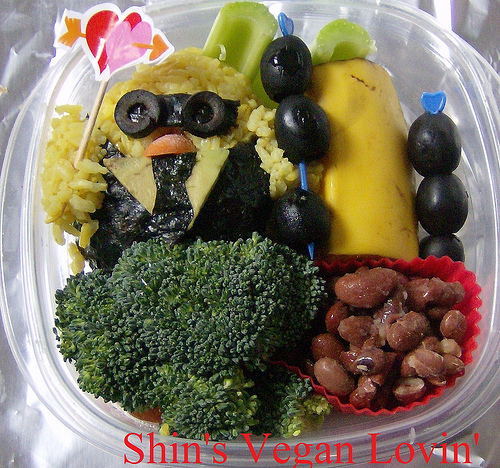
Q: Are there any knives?
A: No, there are no knives.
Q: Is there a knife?
A: No, there are no knives.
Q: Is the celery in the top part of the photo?
A: Yes, the celery is in the top of the image.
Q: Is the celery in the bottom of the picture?
A: No, the celery is in the top of the image.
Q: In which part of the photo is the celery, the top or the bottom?
A: The celery is in the top of the image.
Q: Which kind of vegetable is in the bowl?
A: The vegetable is a celery.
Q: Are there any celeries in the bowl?
A: Yes, there is a celery in the bowl.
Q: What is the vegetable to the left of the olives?
A: The vegetable is a celery.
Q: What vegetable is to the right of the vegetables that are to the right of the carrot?
A: The vegetable is an olive.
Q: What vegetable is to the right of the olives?
A: The vegetable is an olive.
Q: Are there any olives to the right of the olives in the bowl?
A: Yes, there is an olive to the right of the olives.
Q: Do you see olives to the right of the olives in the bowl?
A: Yes, there is an olive to the right of the olives.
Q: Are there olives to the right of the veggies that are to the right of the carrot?
A: Yes, there is an olive to the right of the olives.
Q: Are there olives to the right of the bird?
A: Yes, there is an olive to the right of the bird.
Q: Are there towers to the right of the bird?
A: No, there is an olive to the right of the bird.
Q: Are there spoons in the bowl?
A: No, there is an olive in the bowl.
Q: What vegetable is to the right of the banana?
A: The vegetable is an olive.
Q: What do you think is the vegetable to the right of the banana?
A: The vegetable is an olive.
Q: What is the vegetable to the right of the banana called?
A: The vegetable is an olive.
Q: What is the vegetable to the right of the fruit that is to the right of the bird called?
A: The vegetable is an olive.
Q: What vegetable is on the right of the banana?
A: The vegetable is an olive.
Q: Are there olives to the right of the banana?
A: Yes, there is an olive to the right of the banana.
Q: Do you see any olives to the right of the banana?
A: Yes, there is an olive to the right of the banana.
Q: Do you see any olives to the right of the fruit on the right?
A: Yes, there is an olive to the right of the banana.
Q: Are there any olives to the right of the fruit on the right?
A: Yes, there is an olive to the right of the banana.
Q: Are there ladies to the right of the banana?
A: No, there is an olive to the right of the banana.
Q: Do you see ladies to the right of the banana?
A: No, there is an olive to the right of the banana.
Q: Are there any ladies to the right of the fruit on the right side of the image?
A: No, there is an olive to the right of the banana.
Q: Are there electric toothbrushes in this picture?
A: No, there are no electric toothbrushes.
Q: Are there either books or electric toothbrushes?
A: No, there are no electric toothbrushes or books.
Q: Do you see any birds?
A: Yes, there is a bird.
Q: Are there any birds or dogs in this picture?
A: Yes, there is a bird.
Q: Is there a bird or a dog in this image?
A: Yes, there is a bird.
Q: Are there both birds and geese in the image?
A: No, there is a bird but no geese.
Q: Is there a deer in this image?
A: No, there is no deer.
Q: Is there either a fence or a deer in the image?
A: No, there are no deer or fences.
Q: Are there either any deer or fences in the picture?
A: No, there are no deer or fences.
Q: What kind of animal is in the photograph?
A: The animal is a bird.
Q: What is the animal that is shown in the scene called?
A: The animal is a bird.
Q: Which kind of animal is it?
A: The animal is a bird.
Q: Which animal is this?
A: This is a bird.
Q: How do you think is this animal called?
A: This is a bird.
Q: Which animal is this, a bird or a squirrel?
A: This is a bird.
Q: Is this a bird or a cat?
A: This is a bird.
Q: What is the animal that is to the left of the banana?
A: The animal is a bird.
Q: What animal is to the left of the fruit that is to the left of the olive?
A: The animal is a bird.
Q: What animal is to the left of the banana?
A: The animal is a bird.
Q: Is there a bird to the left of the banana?
A: Yes, there is a bird to the left of the banana.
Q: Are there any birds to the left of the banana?
A: Yes, there is a bird to the left of the banana.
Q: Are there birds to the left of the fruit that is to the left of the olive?
A: Yes, there is a bird to the left of the banana.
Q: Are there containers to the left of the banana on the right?
A: No, there is a bird to the left of the banana.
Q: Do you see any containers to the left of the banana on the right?
A: No, there is a bird to the left of the banana.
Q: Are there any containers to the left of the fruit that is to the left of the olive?
A: No, there is a bird to the left of the banana.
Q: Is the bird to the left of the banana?
A: Yes, the bird is to the left of the banana.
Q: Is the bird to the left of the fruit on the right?
A: Yes, the bird is to the left of the banana.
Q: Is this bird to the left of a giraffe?
A: No, the bird is to the left of the banana.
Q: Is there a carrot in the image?
A: Yes, there is a carrot.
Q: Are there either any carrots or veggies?
A: Yes, there is a carrot.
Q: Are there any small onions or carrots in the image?
A: Yes, there is a small carrot.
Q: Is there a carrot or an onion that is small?
A: Yes, the carrot is small.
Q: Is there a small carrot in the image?
A: Yes, there is a small carrot.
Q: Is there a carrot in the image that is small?
A: Yes, there is a carrot that is small.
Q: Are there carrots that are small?
A: Yes, there is a carrot that is small.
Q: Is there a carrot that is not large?
A: Yes, there is a small carrot.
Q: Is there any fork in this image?
A: No, there are no forks.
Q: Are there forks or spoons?
A: No, there are no forks or spoons.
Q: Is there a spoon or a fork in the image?
A: No, there are no forks or spoons.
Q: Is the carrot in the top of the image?
A: Yes, the carrot is in the top of the image.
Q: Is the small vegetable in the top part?
A: Yes, the carrot is in the top of the image.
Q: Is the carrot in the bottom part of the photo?
A: No, the carrot is in the top of the image.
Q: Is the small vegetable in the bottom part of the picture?
A: No, the carrot is in the top of the image.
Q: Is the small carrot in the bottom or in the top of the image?
A: The carrot is in the top of the image.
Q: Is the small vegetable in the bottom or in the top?
A: The carrot is in the top of the image.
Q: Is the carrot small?
A: Yes, the carrot is small.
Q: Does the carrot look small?
A: Yes, the carrot is small.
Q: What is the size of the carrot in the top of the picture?
A: The carrot is small.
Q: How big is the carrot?
A: The carrot is small.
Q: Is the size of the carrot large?
A: No, the carrot is small.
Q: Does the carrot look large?
A: No, the carrot is small.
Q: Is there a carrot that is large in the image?
A: No, there is a carrot but it is small.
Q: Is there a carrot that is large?
A: No, there is a carrot but it is small.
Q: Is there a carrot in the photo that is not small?
A: No, there is a carrot but it is small.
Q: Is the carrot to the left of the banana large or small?
A: The carrot is small.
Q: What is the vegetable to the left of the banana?
A: The vegetable is a carrot.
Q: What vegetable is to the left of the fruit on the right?
A: The vegetable is a carrot.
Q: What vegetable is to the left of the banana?
A: The vegetable is a carrot.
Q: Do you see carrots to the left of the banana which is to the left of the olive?
A: Yes, there is a carrot to the left of the banana.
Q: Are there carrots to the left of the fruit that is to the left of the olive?
A: Yes, there is a carrot to the left of the banana.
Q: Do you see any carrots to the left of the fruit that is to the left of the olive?
A: Yes, there is a carrot to the left of the banana.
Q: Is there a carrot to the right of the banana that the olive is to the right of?
A: No, the carrot is to the left of the banana.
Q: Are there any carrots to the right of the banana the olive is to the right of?
A: No, the carrot is to the left of the banana.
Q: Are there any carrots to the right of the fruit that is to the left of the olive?
A: No, the carrot is to the left of the banana.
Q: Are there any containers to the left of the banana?
A: No, there is a carrot to the left of the banana.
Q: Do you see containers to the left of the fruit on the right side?
A: No, there is a carrot to the left of the banana.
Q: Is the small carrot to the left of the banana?
A: Yes, the carrot is to the left of the banana.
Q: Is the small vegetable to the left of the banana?
A: Yes, the carrot is to the left of the banana.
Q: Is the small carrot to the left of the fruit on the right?
A: Yes, the carrot is to the left of the banana.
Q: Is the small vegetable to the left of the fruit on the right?
A: Yes, the carrot is to the left of the banana.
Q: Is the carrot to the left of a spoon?
A: No, the carrot is to the left of the banana.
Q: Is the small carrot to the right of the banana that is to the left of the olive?
A: No, the carrot is to the left of the banana.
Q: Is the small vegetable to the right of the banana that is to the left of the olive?
A: No, the carrot is to the left of the banana.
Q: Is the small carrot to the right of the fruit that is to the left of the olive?
A: No, the carrot is to the left of the banana.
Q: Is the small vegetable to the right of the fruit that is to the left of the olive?
A: No, the carrot is to the left of the banana.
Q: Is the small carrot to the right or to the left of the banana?
A: The carrot is to the left of the banana.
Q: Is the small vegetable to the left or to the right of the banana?
A: The carrot is to the left of the banana.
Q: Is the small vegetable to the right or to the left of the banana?
A: The carrot is to the left of the banana.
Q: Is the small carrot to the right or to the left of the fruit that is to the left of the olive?
A: The carrot is to the left of the banana.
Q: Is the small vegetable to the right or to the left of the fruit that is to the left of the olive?
A: The carrot is to the left of the banana.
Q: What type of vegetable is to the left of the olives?
A: The vegetable is a carrot.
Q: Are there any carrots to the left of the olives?
A: Yes, there is a carrot to the left of the olives.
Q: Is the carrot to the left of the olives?
A: Yes, the carrot is to the left of the olives.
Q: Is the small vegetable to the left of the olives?
A: Yes, the carrot is to the left of the olives.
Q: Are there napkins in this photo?
A: No, there are no napkins.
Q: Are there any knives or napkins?
A: No, there are no napkins or knives.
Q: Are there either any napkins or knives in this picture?
A: No, there are no napkins or knives.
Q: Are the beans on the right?
A: Yes, the beans are on the right of the image.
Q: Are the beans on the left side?
A: No, the beans are on the right of the image.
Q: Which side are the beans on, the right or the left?
A: The beans are on the right of the image.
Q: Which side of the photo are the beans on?
A: The beans are on the right of the image.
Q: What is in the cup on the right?
A: The beans are in the cup.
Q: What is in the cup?
A: The beans are in the cup.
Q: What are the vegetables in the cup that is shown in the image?
A: The vegetables are beans.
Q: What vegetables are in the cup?
A: The vegetables are beans.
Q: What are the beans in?
A: The beans are in the cup.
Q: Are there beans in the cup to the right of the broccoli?
A: Yes, there are beans in the cup.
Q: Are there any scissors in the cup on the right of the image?
A: No, there are beans in the cup.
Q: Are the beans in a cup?
A: Yes, the beans are in a cup.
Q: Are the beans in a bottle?
A: No, the beans are in a cup.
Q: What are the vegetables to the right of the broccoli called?
A: The vegetables are beans.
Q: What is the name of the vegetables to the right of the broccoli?
A: The vegetables are beans.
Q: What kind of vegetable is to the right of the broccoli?
A: The vegetables are beans.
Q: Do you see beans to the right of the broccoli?
A: Yes, there are beans to the right of the broccoli.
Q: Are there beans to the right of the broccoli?
A: Yes, there are beans to the right of the broccoli.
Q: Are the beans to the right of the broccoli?
A: Yes, the beans are to the right of the broccoli.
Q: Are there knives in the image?
A: No, there are no knives.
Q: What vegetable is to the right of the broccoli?
A: The vegetable is an olive.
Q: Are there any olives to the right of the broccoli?
A: Yes, there is an olive to the right of the broccoli.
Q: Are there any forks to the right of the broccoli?
A: No, there is an olive to the right of the broccoli.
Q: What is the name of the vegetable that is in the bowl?
A: The vegetable is an olive.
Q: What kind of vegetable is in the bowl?
A: The vegetable is an olive.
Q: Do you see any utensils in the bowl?
A: No, there is an olive in the bowl.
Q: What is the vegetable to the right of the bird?
A: The vegetable is an olive.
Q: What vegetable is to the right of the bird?
A: The vegetable is an olive.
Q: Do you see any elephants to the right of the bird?
A: No, there is an olive to the right of the bird.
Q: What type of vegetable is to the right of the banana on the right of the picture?
A: The vegetable is an olive.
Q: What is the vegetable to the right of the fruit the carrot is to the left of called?
A: The vegetable is an olive.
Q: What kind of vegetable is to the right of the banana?
A: The vegetable is an olive.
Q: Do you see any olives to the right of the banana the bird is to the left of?
A: Yes, there is an olive to the right of the banana.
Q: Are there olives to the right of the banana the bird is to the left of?
A: Yes, there is an olive to the right of the banana.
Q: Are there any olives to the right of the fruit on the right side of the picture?
A: Yes, there is an olive to the right of the banana.